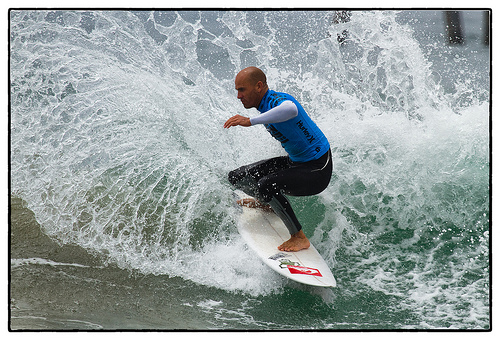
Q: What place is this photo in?
A: It is at the ocean.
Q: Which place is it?
A: It is an ocean.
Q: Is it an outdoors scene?
A: Yes, it is outdoors.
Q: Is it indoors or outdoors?
A: It is outdoors.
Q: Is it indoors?
A: No, it is outdoors.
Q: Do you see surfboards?
A: Yes, there is a surfboard.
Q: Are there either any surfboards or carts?
A: Yes, there is a surfboard.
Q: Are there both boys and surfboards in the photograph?
A: No, there is a surfboard but no boys.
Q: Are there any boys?
A: No, there are no boys.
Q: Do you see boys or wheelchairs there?
A: No, there are no boys or wheelchairs.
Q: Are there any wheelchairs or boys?
A: No, there are no boys or wheelchairs.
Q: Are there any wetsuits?
A: Yes, there is a wetsuit.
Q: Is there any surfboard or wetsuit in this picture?
A: Yes, there is a wetsuit.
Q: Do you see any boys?
A: No, there are no boys.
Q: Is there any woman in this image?
A: No, there are no women.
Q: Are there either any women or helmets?
A: No, there are no women or helmets.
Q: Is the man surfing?
A: Yes, the man is surfing.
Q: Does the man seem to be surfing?
A: Yes, the man is surfing.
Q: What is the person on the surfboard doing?
A: The man is surfing.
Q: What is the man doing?
A: The man is surfing.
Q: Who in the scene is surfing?
A: The man is surfing.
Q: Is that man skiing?
A: No, the man is surfing.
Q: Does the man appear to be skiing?
A: No, the man is surfing.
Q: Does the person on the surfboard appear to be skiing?
A: No, the man is surfing.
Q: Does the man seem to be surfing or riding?
A: The man is surfing.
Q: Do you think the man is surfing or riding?
A: The man is surfing.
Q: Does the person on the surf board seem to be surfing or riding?
A: The man is surfing.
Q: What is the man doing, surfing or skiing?
A: The man is surfing.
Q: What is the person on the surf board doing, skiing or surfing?
A: The man is surfing.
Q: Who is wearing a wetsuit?
A: The man is wearing a wetsuit.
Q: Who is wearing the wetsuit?
A: The man is wearing a wetsuit.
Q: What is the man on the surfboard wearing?
A: The man is wearing a wet suit.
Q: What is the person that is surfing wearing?
A: The man is wearing a wet suit.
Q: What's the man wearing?
A: The man is wearing a wet suit.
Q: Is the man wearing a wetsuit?
A: Yes, the man is wearing a wetsuit.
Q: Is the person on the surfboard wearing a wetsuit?
A: Yes, the man is wearing a wetsuit.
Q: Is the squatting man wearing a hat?
A: No, the man is wearing a wetsuit.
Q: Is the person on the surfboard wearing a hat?
A: No, the man is wearing a wetsuit.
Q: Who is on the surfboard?
A: The man is on the surfboard.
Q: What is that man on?
A: The man is on the surfboard.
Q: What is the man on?
A: The man is on the surfboard.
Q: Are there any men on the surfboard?
A: Yes, there is a man on the surfboard.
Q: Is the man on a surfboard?
A: Yes, the man is on a surfboard.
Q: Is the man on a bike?
A: No, the man is on a surfboard.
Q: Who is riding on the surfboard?
A: The man is riding on the surfboard.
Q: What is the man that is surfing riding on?
A: The man is riding on the surfboard.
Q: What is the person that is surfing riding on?
A: The man is riding on the surfboard.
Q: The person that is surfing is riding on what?
A: The man is riding on the surfboard.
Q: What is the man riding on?
A: The man is riding on the surfboard.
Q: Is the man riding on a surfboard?
A: Yes, the man is riding on a surfboard.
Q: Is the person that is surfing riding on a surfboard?
A: Yes, the man is riding on a surfboard.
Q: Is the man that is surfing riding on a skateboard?
A: No, the man is riding on a surfboard.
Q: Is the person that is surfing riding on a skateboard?
A: No, the man is riding on a surfboard.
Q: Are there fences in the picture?
A: No, there are no fences.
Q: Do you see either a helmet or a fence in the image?
A: No, there are no fences or helmets.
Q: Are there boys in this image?
A: No, there are no boys.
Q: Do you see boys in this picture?
A: No, there are no boys.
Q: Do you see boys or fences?
A: No, there are no boys or fences.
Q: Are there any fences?
A: No, there are no fences.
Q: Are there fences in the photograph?
A: No, there are no fences.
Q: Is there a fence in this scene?
A: No, there are no fences.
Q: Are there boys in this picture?
A: No, there are no boys.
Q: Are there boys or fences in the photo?
A: No, there are no boys or fences.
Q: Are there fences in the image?
A: No, there are no fences.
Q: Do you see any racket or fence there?
A: No, there are no fences or rackets.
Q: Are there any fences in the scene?
A: No, there are no fences.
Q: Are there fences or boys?
A: No, there are no fences or boys.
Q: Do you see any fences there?
A: No, there are no fences.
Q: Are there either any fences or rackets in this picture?
A: No, there are no fences or rackets.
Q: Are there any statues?
A: No, there are no statues.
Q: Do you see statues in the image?
A: No, there are no statues.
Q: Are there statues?
A: No, there are no statues.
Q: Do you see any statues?
A: No, there are no statues.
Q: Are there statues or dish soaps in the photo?
A: No, there are no statues or dish soaps.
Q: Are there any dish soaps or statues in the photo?
A: No, there are no statues or dish soaps.